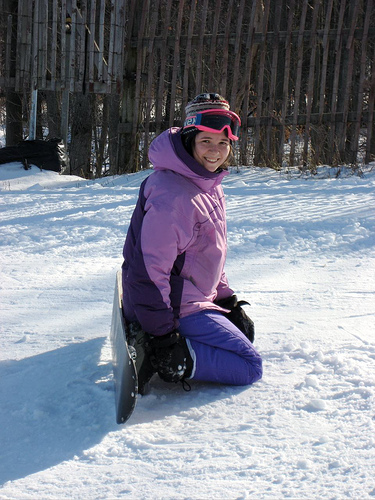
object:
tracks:
[0, 349, 368, 459]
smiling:
[202, 149, 224, 166]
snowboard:
[105, 267, 142, 430]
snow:
[0, 159, 86, 187]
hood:
[145, 123, 229, 193]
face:
[193, 125, 233, 175]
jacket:
[118, 124, 230, 339]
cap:
[185, 90, 231, 115]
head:
[178, 83, 242, 175]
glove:
[144, 327, 193, 389]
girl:
[110, 88, 266, 392]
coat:
[114, 125, 230, 341]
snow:
[0, 164, 375, 500]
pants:
[176, 309, 263, 388]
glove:
[209, 292, 257, 349]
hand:
[215, 288, 256, 344]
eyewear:
[196, 113, 242, 141]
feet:
[133, 340, 164, 403]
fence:
[0, 0, 375, 177]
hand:
[151, 329, 190, 387]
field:
[0, 159, 375, 500]